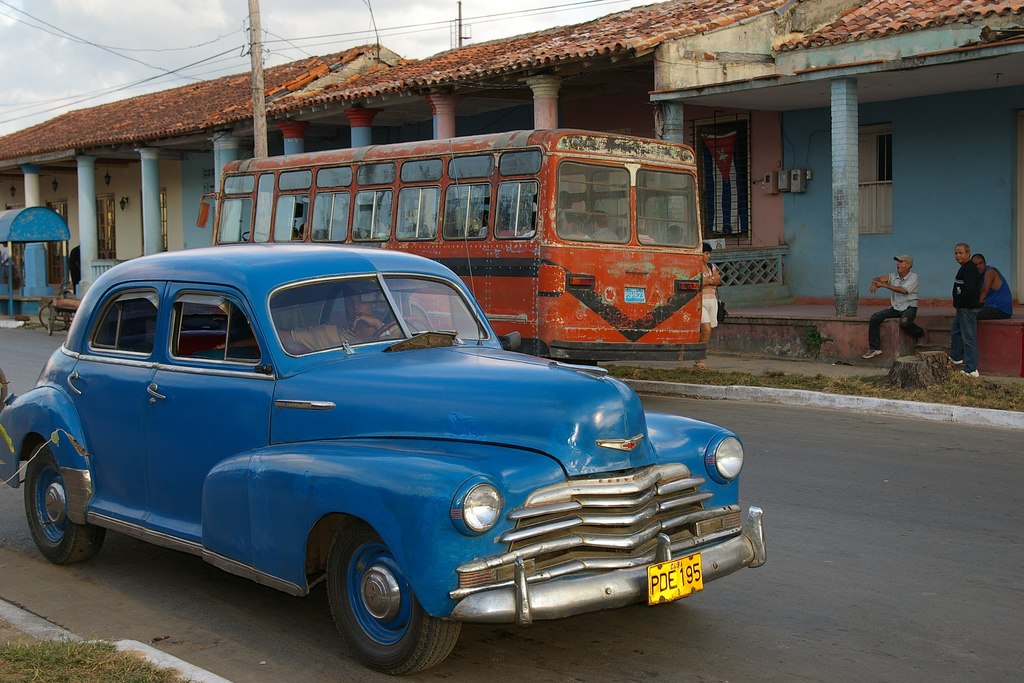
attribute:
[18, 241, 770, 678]
car — blue, vintage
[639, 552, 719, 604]
plate — yellow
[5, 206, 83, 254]
covering — blue, metal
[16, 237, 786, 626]
car — blue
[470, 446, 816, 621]
grill — metal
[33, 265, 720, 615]
car — vintage